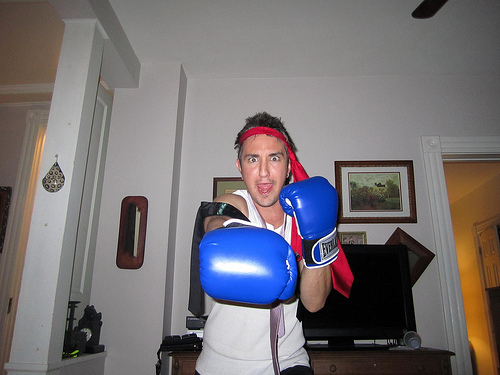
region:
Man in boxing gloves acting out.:
[195, 112, 353, 359]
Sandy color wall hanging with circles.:
[40, 153, 68, 195]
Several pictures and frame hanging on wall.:
[198, 154, 443, 289]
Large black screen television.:
[292, 228, 422, 352]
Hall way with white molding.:
[422, 129, 497, 369]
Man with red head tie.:
[193, 103, 332, 370]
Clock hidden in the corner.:
[76, 300, 107, 356]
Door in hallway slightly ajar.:
[466, 215, 494, 370]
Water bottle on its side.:
[400, 327, 422, 352]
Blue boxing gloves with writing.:
[189, 175, 344, 310]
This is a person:
[180, 97, 363, 367]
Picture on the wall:
[321, 144, 438, 231]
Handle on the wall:
[107, 195, 154, 279]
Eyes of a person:
[239, 146, 289, 166]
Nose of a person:
[258, 165, 271, 180]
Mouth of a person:
[252, 175, 276, 195]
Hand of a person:
[193, 189, 251, 260]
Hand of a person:
[289, 205, 345, 334]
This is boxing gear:
[183, 226, 310, 307]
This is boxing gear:
[280, 171, 356, 256]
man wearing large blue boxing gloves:
[195, 175, 351, 307]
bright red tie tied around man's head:
[233, 110, 361, 299]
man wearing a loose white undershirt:
[195, 186, 312, 373]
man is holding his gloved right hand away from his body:
[195, 111, 344, 312]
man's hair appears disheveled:
[233, 109, 298, 154]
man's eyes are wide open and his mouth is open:
[237, 115, 289, 207]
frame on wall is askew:
[376, 225, 435, 287]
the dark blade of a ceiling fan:
[408, 1, 449, 20]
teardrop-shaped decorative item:
[39, 150, 70, 195]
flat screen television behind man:
[198, 111, 416, 345]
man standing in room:
[201, 113, 334, 371]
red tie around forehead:
[238, 127, 285, 144]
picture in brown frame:
[331, 158, 418, 223]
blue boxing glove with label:
[281, 175, 339, 267]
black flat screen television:
[306, 242, 416, 350]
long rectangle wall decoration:
[112, 194, 148, 271]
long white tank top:
[206, 187, 305, 372]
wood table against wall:
[313, 343, 460, 372]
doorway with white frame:
[423, 135, 498, 332]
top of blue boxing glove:
[199, 229, 296, 298]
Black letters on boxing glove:
[319, 232, 339, 256]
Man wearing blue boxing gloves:
[189, 109, 355, 374]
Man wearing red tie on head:
[188, 110, 355, 374]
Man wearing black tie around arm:
[185, 109, 355, 374]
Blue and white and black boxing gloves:
[276, 173, 343, 268]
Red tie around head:
[236, 125, 353, 295]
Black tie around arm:
[187, 200, 254, 321]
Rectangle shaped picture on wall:
[331, 157, 418, 225]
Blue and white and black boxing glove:
[200, 219, 300, 309]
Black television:
[298, 243, 419, 350]